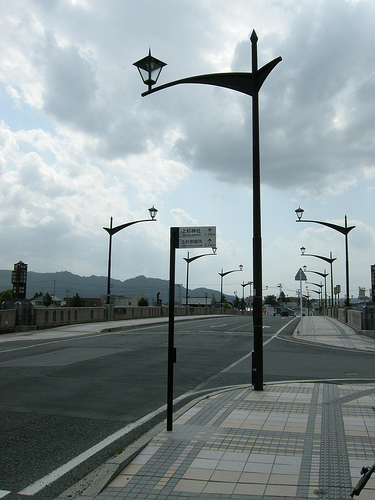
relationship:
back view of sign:
[166, 209, 229, 265] [168, 219, 221, 259]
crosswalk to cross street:
[297, 303, 372, 358] [6, 303, 374, 493]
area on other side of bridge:
[24, 283, 239, 342] [7, 287, 242, 327]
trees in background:
[19, 259, 302, 330] [16, 162, 374, 443]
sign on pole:
[166, 209, 229, 265] [158, 219, 191, 446]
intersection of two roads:
[12, 236, 325, 497] [166, 274, 374, 411]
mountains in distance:
[13, 247, 250, 312] [12, 236, 325, 497]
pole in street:
[158, 219, 191, 446] [12, 236, 325, 497]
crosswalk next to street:
[294, 303, 375, 357] [12, 236, 325, 497]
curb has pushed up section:
[297, 303, 372, 358] [98, 303, 239, 333]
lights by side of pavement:
[135, 28, 312, 403] [0, 313, 301, 500]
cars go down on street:
[221, 290, 299, 333] [12, 236, 325, 497]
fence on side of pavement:
[24, 283, 239, 342] [0, 313, 301, 500]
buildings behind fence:
[45, 288, 171, 322] [41, 292, 247, 328]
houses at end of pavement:
[24, 283, 239, 342] [0, 313, 301, 500]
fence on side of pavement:
[41, 292, 247, 328] [0, 313, 301, 500]